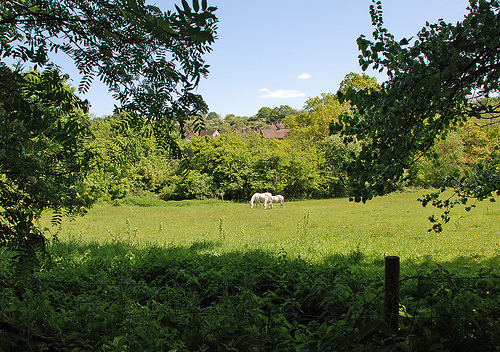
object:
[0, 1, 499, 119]
sky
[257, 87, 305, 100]
clouds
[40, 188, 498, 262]
grass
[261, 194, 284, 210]
horses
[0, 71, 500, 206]
trees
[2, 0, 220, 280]
tree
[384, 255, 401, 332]
fencepost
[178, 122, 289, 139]
roofs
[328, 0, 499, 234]
branches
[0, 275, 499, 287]
wire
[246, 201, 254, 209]
head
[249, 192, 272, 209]
horse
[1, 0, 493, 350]
scene